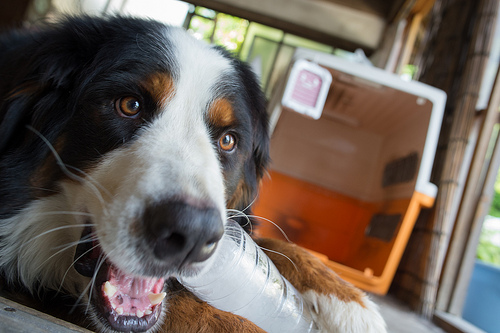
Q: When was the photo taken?
A: Daytime.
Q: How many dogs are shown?
A: One.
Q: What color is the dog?
A: Black and white.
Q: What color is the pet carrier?
A: Orange and white.